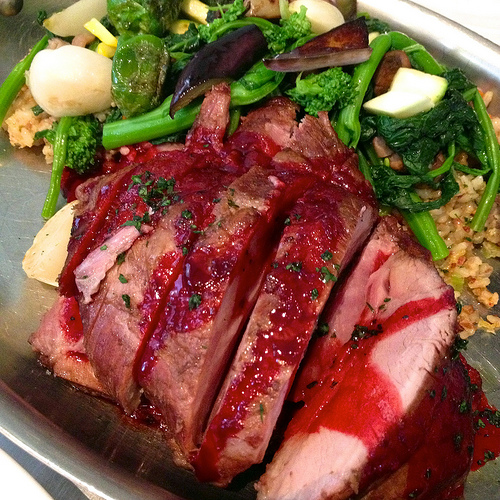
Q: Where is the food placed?
A: On a platter.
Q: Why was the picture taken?
A: To capture the food.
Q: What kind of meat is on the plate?
A: Beef.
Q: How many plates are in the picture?
A: One.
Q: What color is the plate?
A: Silver.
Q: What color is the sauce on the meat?
A: Red.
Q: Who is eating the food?
A: No one.